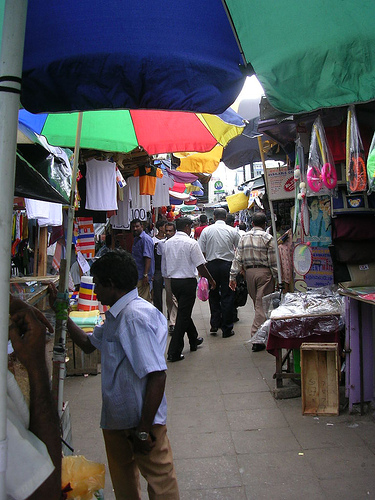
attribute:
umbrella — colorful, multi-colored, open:
[15, 105, 247, 160]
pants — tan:
[100, 429, 180, 497]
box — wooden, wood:
[299, 341, 341, 418]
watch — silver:
[134, 430, 151, 442]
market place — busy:
[0, 0, 372, 499]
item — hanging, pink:
[306, 115, 342, 196]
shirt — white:
[163, 235, 205, 280]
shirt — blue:
[91, 302, 166, 426]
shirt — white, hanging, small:
[85, 162, 119, 212]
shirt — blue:
[306, 213, 324, 242]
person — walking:
[197, 205, 244, 340]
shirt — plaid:
[230, 232, 278, 273]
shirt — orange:
[134, 167, 165, 195]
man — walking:
[228, 213, 283, 352]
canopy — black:
[221, 118, 278, 171]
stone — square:
[229, 410, 283, 431]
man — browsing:
[48, 251, 186, 499]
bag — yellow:
[55, 454, 107, 494]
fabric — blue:
[22, 1, 248, 116]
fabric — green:
[227, 1, 373, 115]